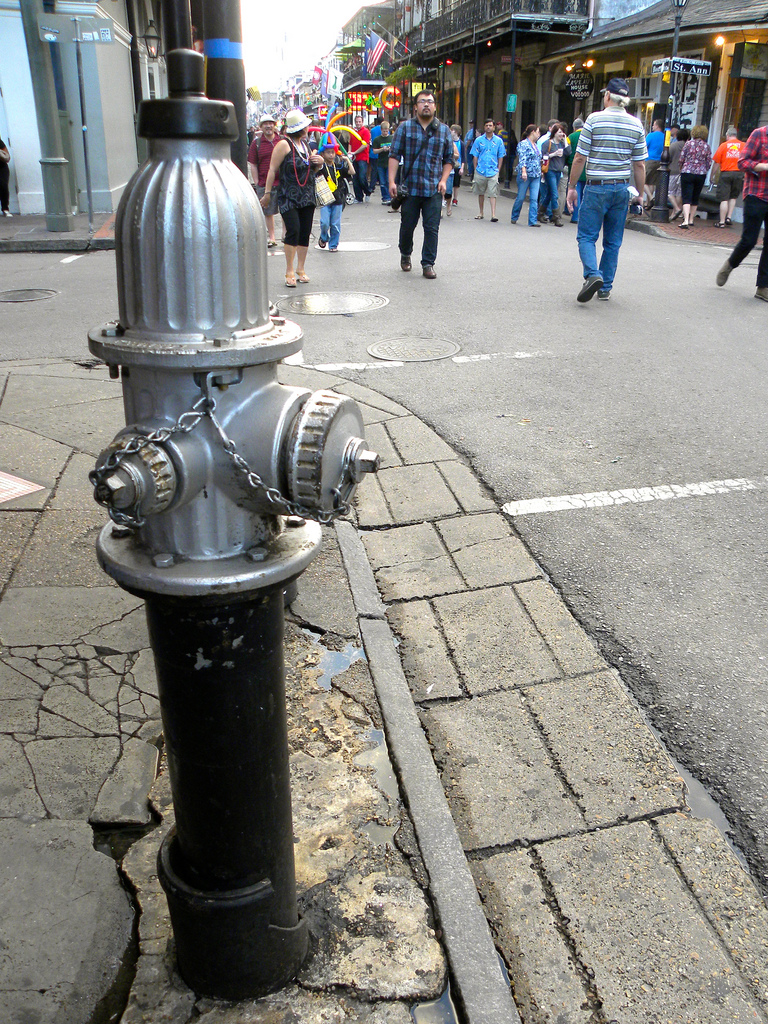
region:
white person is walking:
[385, 91, 461, 272]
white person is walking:
[566, 75, 648, 299]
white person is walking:
[679, 123, 715, 221]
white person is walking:
[714, 123, 741, 228]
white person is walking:
[511, 124, 547, 224]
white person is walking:
[470, 119, 506, 219]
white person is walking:
[264, 107, 322, 288]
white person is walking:
[315, 143, 353, 249]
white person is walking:
[248, 115, 282, 246]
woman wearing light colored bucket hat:
[259, 108, 324, 284]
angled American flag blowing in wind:
[365, 27, 394, 73]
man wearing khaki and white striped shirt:
[566, 79, 648, 302]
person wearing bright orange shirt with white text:
[712, 127, 750, 226]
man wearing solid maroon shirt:
[248, 115, 286, 246]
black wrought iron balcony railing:
[389, 0, 588, 60]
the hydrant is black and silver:
[16, 58, 408, 981]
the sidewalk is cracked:
[1, 574, 150, 831]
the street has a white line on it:
[531, 457, 740, 573]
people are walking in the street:
[244, 25, 747, 362]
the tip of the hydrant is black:
[121, 20, 269, 194]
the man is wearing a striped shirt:
[562, 74, 646, 301]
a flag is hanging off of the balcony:
[333, 15, 437, 76]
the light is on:
[675, 8, 744, 62]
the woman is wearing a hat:
[263, 96, 349, 275]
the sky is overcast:
[232, 0, 380, 114]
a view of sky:
[285, 35, 333, 66]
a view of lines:
[498, 838, 579, 954]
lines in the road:
[496, 819, 602, 963]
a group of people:
[329, 89, 572, 261]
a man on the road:
[481, 65, 668, 404]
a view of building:
[280, 30, 665, 172]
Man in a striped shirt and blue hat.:
[562, 72, 655, 312]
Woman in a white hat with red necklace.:
[259, 109, 324, 293]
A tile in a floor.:
[431, 573, 562, 689]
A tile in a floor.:
[518, 574, 598, 682]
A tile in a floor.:
[382, 593, 466, 703]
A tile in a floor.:
[359, 520, 464, 609]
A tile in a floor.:
[424, 504, 551, 589]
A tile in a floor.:
[440, 455, 494, 515]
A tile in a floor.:
[417, 672, 587, 849]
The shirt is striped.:
[582, 113, 654, 179]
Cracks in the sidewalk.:
[18, 613, 180, 799]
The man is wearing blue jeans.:
[567, 180, 637, 280]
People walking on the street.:
[250, 91, 614, 281]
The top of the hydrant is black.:
[126, 44, 230, 139]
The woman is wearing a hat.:
[279, 89, 314, 131]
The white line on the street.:
[505, 460, 766, 533]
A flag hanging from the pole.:
[346, 16, 396, 74]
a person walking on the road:
[570, 113, 640, 332]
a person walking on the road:
[390, 78, 458, 297]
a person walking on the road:
[263, 117, 368, 264]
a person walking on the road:
[732, 69, 762, 327]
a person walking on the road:
[541, 91, 562, 218]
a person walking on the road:
[509, 124, 539, 222]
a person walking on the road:
[318, 60, 416, 253]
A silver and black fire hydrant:
[68, 28, 391, 1007]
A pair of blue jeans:
[556, 165, 634, 305]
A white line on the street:
[481, 455, 764, 538]